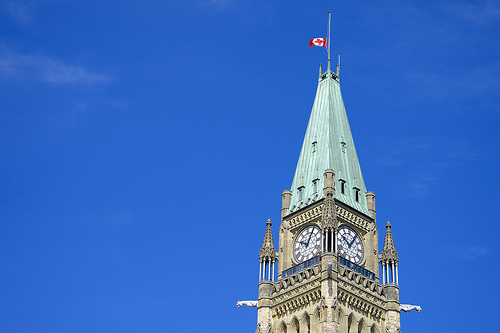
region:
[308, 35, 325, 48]
Red and white flag on top of tower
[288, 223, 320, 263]
Round white clock on tower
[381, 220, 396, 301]
Grey finnial on side of tower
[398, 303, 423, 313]
Grey gargoyle on side of tower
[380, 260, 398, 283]
Thin grey concrete columns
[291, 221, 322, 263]
Black Roman numerals on clock face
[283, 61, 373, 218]
Light blue pointed roof on tower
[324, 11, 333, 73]
Metal flagpole on top of tower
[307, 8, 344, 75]
Flag on flagpole flying at half mast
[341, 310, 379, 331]
Small windows on side of tower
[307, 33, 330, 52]
Canadian flag flying over building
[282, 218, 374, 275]
A building clock tower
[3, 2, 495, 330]
Bright blue sunny sky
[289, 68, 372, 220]
A mint green roof tower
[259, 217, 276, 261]
A decorative spindle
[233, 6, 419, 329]
The top of a tall building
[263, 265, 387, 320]
Decorative trim on a building tower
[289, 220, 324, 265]
Clock showing time of 10:05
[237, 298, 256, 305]
A decorative piece sticking off the building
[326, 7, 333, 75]
Flagpole on top of a building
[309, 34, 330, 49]
flag with a red cross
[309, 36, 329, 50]
red cross with a white background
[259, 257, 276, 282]
columns of an architectural decoration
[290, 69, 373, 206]
a green cap on the tower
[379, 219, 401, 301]
an architectural feature on the right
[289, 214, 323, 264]
a clock face on the left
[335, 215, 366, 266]
a clock face on the right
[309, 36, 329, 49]
a flag on top of the tower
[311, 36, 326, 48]
a flag blowing to the left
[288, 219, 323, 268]
a clock saying 10:05 am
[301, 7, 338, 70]
pole with flag on it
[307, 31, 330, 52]
flag banner on top of building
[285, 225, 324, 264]
clock on side of building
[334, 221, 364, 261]
another clock on side of building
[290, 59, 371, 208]
pointed structure on top of clock area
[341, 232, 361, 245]
hands on face of one clock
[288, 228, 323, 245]
hands on face of other clock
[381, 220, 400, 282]
gazebo structure on corner of building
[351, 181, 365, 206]
slat area on top tower structure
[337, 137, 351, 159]
protruding structure on top tower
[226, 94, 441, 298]
a clock on a building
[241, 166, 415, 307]
a clock on a tower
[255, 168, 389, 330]
a clock on an old building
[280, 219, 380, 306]
an outside clock on a building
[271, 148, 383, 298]
an outside clock on a tower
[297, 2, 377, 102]
a flag on a building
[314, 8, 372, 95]
a flag on a pole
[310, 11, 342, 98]
a flag on a metal pole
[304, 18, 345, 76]
a pole with a flag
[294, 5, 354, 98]
a metal pole with a flag